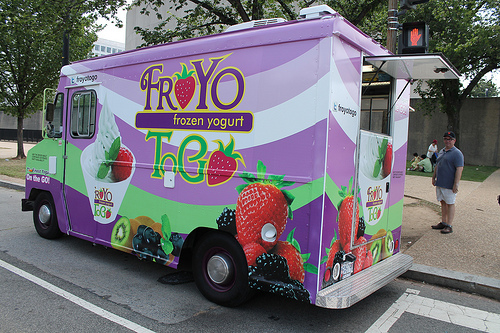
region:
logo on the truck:
[139, 60, 252, 112]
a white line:
[107, 309, 130, 326]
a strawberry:
[241, 187, 278, 215]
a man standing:
[428, 129, 473, 235]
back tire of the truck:
[194, 234, 246, 301]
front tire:
[26, 199, 59, 234]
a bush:
[464, 23, 490, 49]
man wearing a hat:
[440, 125, 457, 140]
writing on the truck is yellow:
[171, 110, 249, 130]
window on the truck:
[71, 93, 100, 135]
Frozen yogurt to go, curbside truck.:
[21, 6, 464, 310]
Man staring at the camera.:
[430, 131, 463, 233]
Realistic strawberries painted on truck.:
[233, 179, 304, 282]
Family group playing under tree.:
[409, 137, 439, 172]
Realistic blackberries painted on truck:
[249, 250, 306, 300]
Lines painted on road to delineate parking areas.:
[360, 288, 499, 331]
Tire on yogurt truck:
[190, 233, 250, 306]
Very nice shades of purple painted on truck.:
[70, 19, 332, 113]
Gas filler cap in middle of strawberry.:
[259, 222, 279, 244]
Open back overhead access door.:
[366, 52, 467, 84]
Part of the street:
[8, 299, 45, 322]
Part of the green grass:
[467, 170, 482, 177]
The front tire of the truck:
[28, 186, 68, 241]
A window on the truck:
[66, 86, 101, 141]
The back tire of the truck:
[186, 228, 266, 312]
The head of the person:
[438, 129, 458, 149]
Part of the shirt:
[443, 164, 448, 184]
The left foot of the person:
[438, 224, 454, 235]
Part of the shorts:
[442, 192, 453, 199]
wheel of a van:
[15, 174, 85, 259]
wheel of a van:
[177, 217, 277, 309]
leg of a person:
[433, 195, 443, 222]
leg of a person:
[444, 197, 464, 225]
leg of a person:
[405, 158, 414, 173]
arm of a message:
[446, 154, 476, 181]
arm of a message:
[427, 154, 442, 181]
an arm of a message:
[448, 160, 473, 183]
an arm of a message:
[423, 158, 444, 181]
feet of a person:
[433, 225, 463, 240]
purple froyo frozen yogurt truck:
[16, 13, 443, 331]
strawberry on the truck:
[207, 135, 238, 189]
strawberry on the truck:
[168, 61, 199, 111]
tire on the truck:
[191, 227, 253, 309]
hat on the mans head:
[428, 125, 461, 148]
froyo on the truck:
[133, 50, 252, 112]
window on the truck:
[48, 92, 66, 137]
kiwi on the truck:
[107, 217, 138, 250]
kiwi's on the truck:
[370, 227, 395, 260]